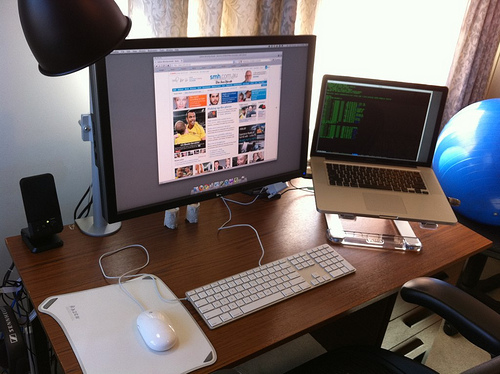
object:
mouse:
[134, 309, 176, 350]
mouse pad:
[33, 274, 219, 374]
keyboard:
[187, 245, 354, 328]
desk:
[2, 169, 494, 374]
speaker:
[20, 174, 62, 251]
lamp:
[18, 0, 131, 77]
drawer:
[368, 320, 442, 364]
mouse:
[361, 190, 407, 212]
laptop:
[309, 74, 461, 225]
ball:
[431, 96, 500, 224]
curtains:
[126, 0, 315, 45]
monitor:
[98, 35, 312, 227]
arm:
[401, 276, 499, 355]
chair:
[285, 276, 500, 373]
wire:
[97, 243, 187, 307]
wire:
[214, 197, 266, 270]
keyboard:
[323, 162, 431, 194]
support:
[161, 206, 183, 230]